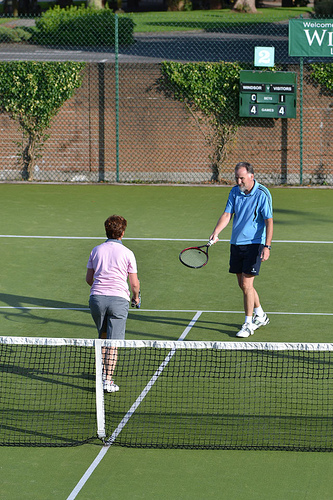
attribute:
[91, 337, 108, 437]
line — white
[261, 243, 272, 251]
watch — black 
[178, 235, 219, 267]
racket — tennis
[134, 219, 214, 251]
line — white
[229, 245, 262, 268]
short — blue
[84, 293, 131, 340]
shorts — grey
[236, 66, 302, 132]
sign — green, black, white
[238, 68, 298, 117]
scoreboard — green 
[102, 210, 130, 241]
brownhair — brown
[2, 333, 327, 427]
tennis net — short, black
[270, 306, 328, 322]
line — horizontal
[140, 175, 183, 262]
floor — dark green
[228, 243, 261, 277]
shorts — dark blue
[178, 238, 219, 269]
racket — red, black